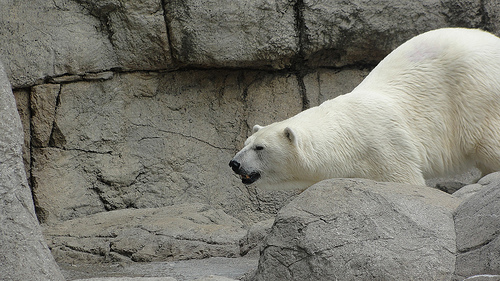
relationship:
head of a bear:
[227, 121, 299, 188] [229, 19, 477, 205]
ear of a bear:
[280, 123, 299, 140] [229, 19, 477, 205]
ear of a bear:
[283, 127, 298, 143] [229, 19, 477, 205]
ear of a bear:
[251, 120, 261, 135] [229, 19, 477, 205]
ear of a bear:
[253, 124, 261, 132] [229, 19, 477, 205]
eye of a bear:
[251, 139, 271, 152] [229, 19, 477, 205]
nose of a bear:
[229, 160, 242, 171] [229, 19, 477, 205]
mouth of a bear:
[236, 167, 267, 191] [222, 15, 464, 214]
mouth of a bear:
[236, 167, 261, 184] [229, 19, 477, 205]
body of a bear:
[226, 14, 471, 215] [229, 19, 477, 205]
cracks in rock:
[22, 74, 89, 232] [29, 74, 189, 217]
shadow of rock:
[133, 62, 329, 103] [106, 0, 366, 168]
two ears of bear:
[242, 121, 302, 141] [222, 15, 464, 214]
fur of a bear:
[416, 109, 459, 159] [229, 19, 477, 205]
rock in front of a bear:
[250, 173, 446, 280] [225, 19, 469, 193]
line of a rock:
[287, 13, 319, 107] [199, 12, 368, 69]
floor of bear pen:
[84, 245, 264, 279] [2, 2, 498, 276]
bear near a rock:
[229, 28, 500, 187] [250, 173, 446, 280]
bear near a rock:
[229, 28, 500, 187] [306, 9, 486, 69]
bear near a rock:
[229, 28, 500, 187] [441, 156, 499, 272]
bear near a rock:
[229, 28, 500, 187] [164, 7, 298, 74]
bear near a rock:
[229, 28, 500, 187] [32, 62, 319, 227]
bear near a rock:
[229, 28, 500, 187] [24, 73, 305, 207]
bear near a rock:
[229, 28, 500, 187] [297, 5, 487, 77]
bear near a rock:
[229, 28, 500, 187] [32, 182, 261, 260]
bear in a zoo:
[229, 28, 500, 187] [6, 4, 487, 280]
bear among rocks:
[229, 28, 500, 187] [4, 2, 498, 276]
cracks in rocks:
[22, 74, 89, 232] [4, 2, 498, 276]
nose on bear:
[222, 153, 243, 173] [229, 28, 500, 187]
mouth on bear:
[236, 167, 261, 184] [229, 28, 500, 187]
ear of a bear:
[283, 127, 298, 143] [229, 28, 500, 187]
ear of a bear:
[253, 124, 261, 132] [229, 28, 500, 187]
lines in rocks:
[153, 7, 373, 141] [4, 2, 498, 276]